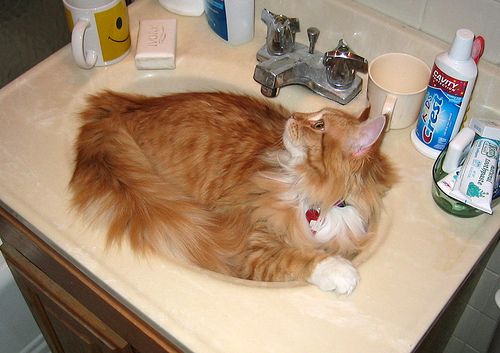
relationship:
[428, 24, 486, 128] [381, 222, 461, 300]
tooth paste on counter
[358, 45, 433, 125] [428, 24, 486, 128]
mug next to tooth paste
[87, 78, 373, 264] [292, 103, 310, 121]
cat has nose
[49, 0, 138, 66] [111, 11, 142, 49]
mug has smiley face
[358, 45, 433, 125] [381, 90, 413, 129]
mug has handle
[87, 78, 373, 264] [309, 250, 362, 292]
cat has paw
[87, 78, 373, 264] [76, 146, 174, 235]
cat has tail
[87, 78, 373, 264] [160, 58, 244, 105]
cat in sink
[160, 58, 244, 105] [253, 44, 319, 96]
sink has tap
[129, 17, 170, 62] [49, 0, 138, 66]
soap near mug